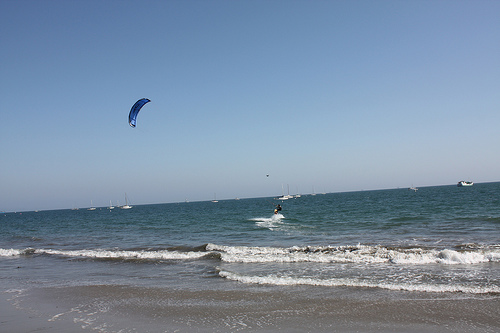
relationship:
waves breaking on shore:
[1, 243, 500, 294] [4, 280, 499, 332]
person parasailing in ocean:
[269, 203, 284, 213] [0, 179, 500, 294]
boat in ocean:
[458, 179, 475, 189] [0, 179, 500, 294]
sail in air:
[127, 95, 152, 131] [1, 1, 500, 214]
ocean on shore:
[0, 179, 500, 294] [4, 280, 499, 332]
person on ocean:
[269, 203, 284, 213] [0, 179, 500, 294]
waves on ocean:
[1, 243, 500, 294] [0, 179, 500, 294]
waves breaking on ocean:
[1, 243, 500, 294] [0, 179, 500, 294]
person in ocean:
[269, 203, 284, 213] [0, 179, 500, 294]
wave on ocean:
[248, 211, 288, 233] [0, 179, 500, 294]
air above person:
[1, 1, 500, 214] [269, 203, 284, 213]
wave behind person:
[248, 211, 288, 233] [269, 203, 284, 213]